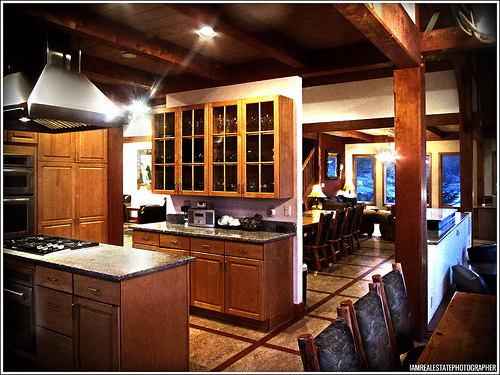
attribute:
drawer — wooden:
[31, 265, 76, 300]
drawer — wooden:
[71, 270, 121, 310]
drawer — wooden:
[218, 239, 263, 259]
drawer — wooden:
[185, 237, 222, 260]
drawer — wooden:
[151, 230, 192, 252]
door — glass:
[241, 93, 274, 193]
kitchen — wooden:
[1, 34, 299, 370]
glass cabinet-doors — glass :
[153, 112, 288, 197]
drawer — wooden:
[62, 267, 125, 304]